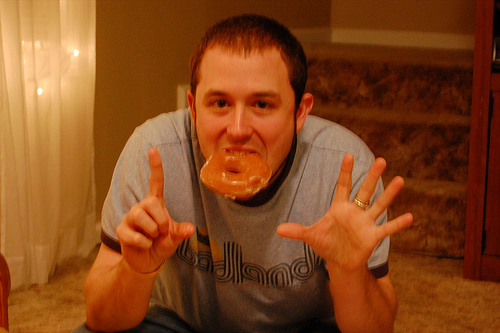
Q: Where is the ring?
A: Right hand.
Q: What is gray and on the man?
A: A shirt.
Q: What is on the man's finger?
A: A ring.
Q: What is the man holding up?
A: Six fingers.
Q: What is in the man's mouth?
A: A doughnut.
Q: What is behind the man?
A: Steps.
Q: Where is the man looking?
A: At the camera.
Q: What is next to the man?
A: Curtains.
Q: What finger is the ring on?
A: Middle finger.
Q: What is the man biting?
A: A doughnut.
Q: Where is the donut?
A: In the man's mouth.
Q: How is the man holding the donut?
A: With his mouth.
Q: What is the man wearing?
A: A gray shirt.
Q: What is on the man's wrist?
A: A bracelet.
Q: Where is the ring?
A: On his finger.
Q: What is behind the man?
A: Stairs.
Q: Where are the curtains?
A: To the left.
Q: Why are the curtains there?
A: To block the window.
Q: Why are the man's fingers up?
A: To count.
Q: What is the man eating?
A: A donut.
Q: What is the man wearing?
A: A shirt.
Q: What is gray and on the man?
A: The shirt.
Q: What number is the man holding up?
A: Six.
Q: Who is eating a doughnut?
A: A man.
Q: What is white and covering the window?
A: The curtains.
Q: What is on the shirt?
A: Writing.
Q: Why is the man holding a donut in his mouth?
A: To use hands.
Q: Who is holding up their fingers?
A: Man with grey shirt.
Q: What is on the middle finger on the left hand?
A: Ring.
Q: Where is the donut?
A: Man's mouth.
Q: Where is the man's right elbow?
A: On his knee.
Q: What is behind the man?
A: Steps.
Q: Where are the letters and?
A: Mans shirt.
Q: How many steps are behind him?
A: Three.